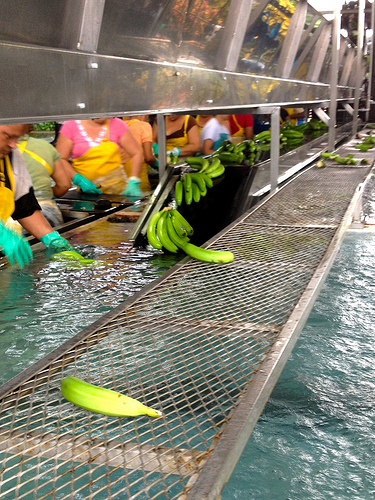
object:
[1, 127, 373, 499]
shelf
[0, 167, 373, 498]
water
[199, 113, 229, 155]
woman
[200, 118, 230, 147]
white shirt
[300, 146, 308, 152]
ground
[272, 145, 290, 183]
ground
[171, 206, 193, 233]
banana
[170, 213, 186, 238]
banana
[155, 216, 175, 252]
banana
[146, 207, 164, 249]
banana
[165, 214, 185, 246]
banana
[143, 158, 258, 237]
bucket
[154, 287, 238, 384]
grate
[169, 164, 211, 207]
bananas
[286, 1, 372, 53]
lights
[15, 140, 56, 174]
strap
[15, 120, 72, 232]
woman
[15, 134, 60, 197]
green shirt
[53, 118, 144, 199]
person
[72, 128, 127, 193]
yellow apron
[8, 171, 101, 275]
arm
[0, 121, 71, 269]
woman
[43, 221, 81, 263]
hand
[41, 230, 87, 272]
gloves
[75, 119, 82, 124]
dot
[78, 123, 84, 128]
dot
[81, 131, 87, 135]
dot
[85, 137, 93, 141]
dot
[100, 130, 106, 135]
dot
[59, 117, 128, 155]
shirt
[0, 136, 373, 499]
grate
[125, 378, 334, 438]
object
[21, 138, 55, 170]
shoulder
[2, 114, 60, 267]
people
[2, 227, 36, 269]
gloves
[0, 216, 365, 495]
rack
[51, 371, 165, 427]
banana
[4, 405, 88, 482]
rack